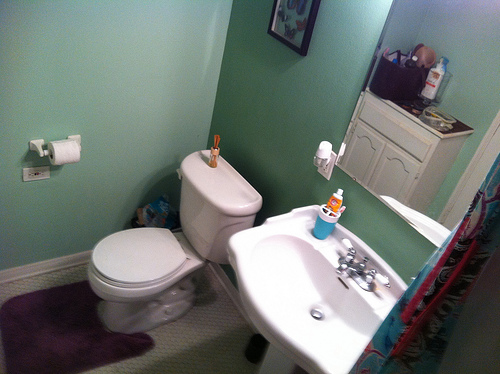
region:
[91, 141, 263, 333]
a white toilet in a bathroom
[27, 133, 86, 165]
a roll of white toilet paper on a rack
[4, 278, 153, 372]
a purple bathroom rug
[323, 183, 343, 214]
top of a tube of toothpaste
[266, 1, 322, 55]
a black frame of pinned butterflies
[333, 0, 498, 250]
a mirror on the wall of a bathroom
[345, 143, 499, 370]
a colorful shower curtain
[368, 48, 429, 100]
a black bag on top of a white cabinet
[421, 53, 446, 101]
a white bottle of body lotion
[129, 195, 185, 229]
a wastebasket full in the corner of the bathroom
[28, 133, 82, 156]
White toilet paper holder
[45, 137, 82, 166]
White roll of toilet paper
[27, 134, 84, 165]
White roll toilet paper on white toilet paper holder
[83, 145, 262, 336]
White toilet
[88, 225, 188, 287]
White toilet seat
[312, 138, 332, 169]
White and clear air freshner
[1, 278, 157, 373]
Purple bathroom rug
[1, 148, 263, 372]
Purple bathroom run in front of white toilet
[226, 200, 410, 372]
White bathroom sink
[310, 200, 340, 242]
Blue and white toothbrush holder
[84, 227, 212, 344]
this is a toilet sink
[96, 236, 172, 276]
this is the lid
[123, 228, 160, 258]
the lid is white in color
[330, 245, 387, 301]
this is a tap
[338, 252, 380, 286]
the tap is shinny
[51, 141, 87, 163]
this is a tissue paper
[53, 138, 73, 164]
the tissue paper is white in color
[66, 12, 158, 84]
this is the wall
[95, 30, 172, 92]
the wall is blue in color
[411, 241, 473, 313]
this is the curtain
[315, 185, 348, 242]
A container holding toothpaste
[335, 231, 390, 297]
A chrome sink faucet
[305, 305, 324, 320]
The metal drain and stopper in the sink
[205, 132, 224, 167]
A reed scent diffuser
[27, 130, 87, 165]
A white toilet paper holder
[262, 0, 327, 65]
Framed art on the wall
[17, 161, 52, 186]
A power port in the wall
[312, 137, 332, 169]
A scent diffuser plugged into the wall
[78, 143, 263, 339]
A white porcelain toilet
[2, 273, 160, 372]
A purple rug on the floor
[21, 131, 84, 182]
bathroom toilet paper holder with paper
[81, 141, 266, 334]
a white tank-style toilet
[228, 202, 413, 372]
a white porcelain pedestal bathroom sink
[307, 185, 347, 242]
blue and white toothbrush holder with toothpaste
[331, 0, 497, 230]
rectangular bathroom mirror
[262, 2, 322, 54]
decorative picture on the bathroom wall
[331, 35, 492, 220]
reflection of cabinet with toiletries in the bathroom mirror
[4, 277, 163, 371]
purple bathroom floor rug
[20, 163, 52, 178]
electrical outlet on the wall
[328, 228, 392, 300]
bathroom faucet with ceramic handles